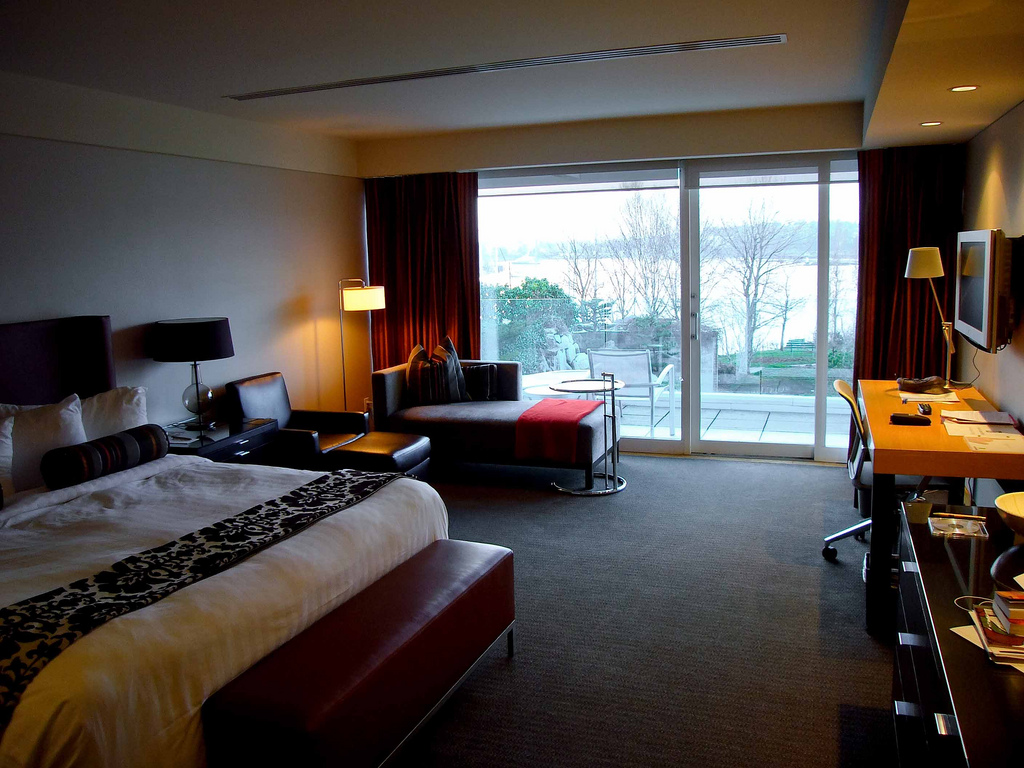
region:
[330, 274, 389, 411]
floor lamp on a metal pole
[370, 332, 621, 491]
brown chaise in a bedroom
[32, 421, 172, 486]
black, gray and red neck pillow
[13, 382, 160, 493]
two white pillows on the bed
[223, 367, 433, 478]
black leather chair beside a floor lamp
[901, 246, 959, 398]
small lamp on top of the desk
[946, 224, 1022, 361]
HD television on the wall above the desk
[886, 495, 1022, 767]
wooden dresser with metal handles on the drawers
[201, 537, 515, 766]
burgundy leather seat in front of the bed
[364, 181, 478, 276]
red curtain on the window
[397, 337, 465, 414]
pillow on the bed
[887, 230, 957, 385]
lamp on the desk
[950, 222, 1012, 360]
tv mounted on the wall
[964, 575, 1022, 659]
books on the desk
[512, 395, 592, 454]
blanket draped over the chair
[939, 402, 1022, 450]
papers on the desk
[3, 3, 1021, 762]
high end hotel room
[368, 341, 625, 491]
brown decorative daybed and throw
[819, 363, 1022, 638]
wood top computer desk and chair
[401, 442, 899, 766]
fine fabric tan carpeting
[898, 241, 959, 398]
attached desk lamp, with tilting arm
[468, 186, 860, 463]
large sliding glassdoor and display windows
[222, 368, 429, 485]
leather single person chair with matching foot rest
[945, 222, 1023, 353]
large flatscreen wall mounted tv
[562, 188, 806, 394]
fall scenery trees with bare branchs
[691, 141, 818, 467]
a window on a building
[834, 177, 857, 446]
a window on a building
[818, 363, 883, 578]
a chair that can roll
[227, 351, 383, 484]
a chair that you sit in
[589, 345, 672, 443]
a chair that is outside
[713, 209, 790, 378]
a tree in a field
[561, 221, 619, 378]
a tree in a field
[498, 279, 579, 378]
a tree in a field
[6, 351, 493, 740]
bed in the room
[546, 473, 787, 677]
carpet in the room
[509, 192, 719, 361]
trees outside the window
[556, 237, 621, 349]
a tree branch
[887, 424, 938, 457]
a desk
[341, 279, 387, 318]
a lamp shade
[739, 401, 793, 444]
the side walk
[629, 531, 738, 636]
the carpet on the floor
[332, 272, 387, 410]
small pole lamp near chair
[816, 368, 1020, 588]
desk and chair in hotel room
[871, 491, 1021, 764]
chest of drawers in hotel room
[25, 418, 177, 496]
bedroll pillow in front of sleeping pillows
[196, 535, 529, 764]
cushioned bench for sitting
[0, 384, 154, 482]
sleeping pillows covered in white pillowcases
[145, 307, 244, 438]
table lamp on bedside table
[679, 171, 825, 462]
door to outside patio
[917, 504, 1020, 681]
miscellaneous literature on top of chest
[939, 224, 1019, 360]
television screen affixed to wall